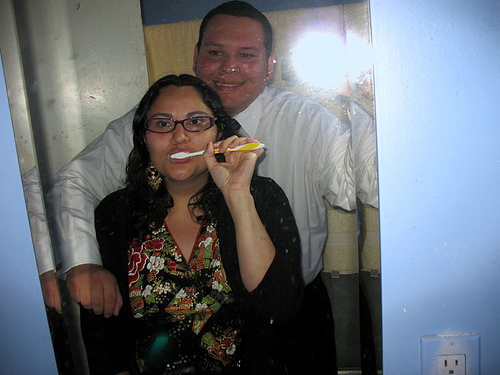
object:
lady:
[64, 87, 276, 373]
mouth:
[149, 133, 219, 193]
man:
[207, 33, 355, 229]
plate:
[407, 325, 488, 371]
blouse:
[121, 210, 251, 371]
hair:
[124, 82, 251, 224]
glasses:
[135, 109, 219, 138]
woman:
[37, 67, 314, 362]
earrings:
[144, 165, 159, 186]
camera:
[278, 8, 360, 115]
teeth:
[163, 151, 197, 163]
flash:
[288, 19, 367, 106]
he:
[46, 3, 391, 372]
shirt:
[56, 80, 370, 272]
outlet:
[425, 337, 475, 369]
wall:
[382, 58, 484, 360]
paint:
[437, 324, 466, 347]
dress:
[93, 181, 305, 373]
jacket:
[91, 164, 307, 364]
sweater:
[84, 173, 309, 369]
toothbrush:
[166, 134, 265, 156]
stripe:
[224, 140, 264, 153]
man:
[51, 9, 384, 371]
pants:
[288, 278, 353, 370]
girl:
[83, 67, 313, 372]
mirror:
[6, 2, 383, 372]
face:
[193, 19, 266, 111]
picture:
[43, 5, 374, 355]